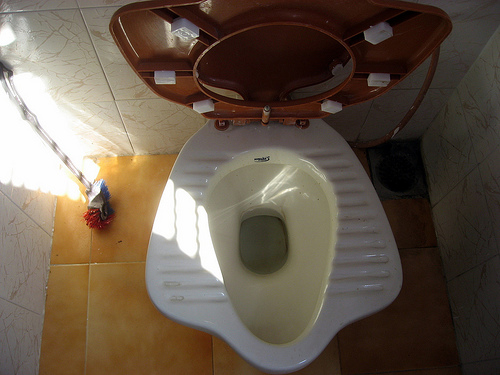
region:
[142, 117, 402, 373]
Odd shaped toilet seat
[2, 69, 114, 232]
Toilet bowl cleaner attached to the wall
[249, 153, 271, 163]
Black logo on a toilet seat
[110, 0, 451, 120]
Odd shaped brown toilet seat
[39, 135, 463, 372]
Light orange tiled floor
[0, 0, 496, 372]
Tiled bathroom walls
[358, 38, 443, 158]
Brown plumbing tube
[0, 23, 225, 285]
Sunlight coming from a window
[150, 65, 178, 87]
White cushions on the bottom of a toilet seat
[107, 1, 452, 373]
Toilet and toilet seat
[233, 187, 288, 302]
tunnel in a toilet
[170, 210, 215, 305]
ridges on a toilet seat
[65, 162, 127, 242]
red and blue toilet brush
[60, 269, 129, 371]
brown tile in a bathroom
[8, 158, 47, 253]
white and gold wall towell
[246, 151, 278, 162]
logo in a toilet bowl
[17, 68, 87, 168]
sunlight on the wall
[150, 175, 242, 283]
sunlight on a toilet seat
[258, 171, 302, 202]
sunlight in the toilet bowl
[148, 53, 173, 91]
white square on the bottom of a toilet seat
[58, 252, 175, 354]
the floor is tiled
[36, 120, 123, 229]
handle on the brush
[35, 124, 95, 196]
the handle is white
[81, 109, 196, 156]
the wall is tiled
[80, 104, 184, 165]
the wall is marble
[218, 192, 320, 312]
water in the toilet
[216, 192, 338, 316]
the water is dirty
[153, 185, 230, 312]
lines on the toilet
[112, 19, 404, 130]
toilet lid is up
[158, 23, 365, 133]
sponges on the toilet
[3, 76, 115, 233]
Toliet scrubber with red and blue bristles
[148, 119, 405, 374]
White toliet with ridged seat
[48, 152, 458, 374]
Brown square tiled floor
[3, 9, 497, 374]
White walls with cracked tan design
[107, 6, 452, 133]
Brown toliet lid with white stoppers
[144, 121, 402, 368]
Dirty white toliet seat with little water in bowl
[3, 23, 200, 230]
Silver toliet cleaner leaning against wall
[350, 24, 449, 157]
Brown cord running to back of toliet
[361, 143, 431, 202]
Square plate with circle in middle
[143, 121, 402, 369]
White porcelain toliet with black logo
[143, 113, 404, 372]
oddly shaped white toilet in white bathroom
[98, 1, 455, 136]
brown toilet seat lifted up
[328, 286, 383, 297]
ridge in the porcelain toilet for the toilet seat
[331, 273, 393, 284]
ridge in the porcelain toilet for the toilet seat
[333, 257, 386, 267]
ridge in the porcelain toilet for the toilet seat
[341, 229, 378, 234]
ridge in the porcelain toilet for the toilet seat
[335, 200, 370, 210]
ridge in the porcelain toilet for the toilet seat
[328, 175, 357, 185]
ridge in the porcelain toilet for the toilet seat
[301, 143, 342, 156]
ridge in the porcelain toilet for the toilet seat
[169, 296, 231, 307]
ridge in the porcelain toilet for the toilet seat